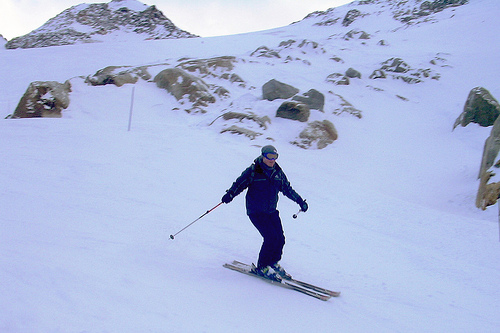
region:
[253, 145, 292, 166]
Person wearing gray hat.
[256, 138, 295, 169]
Blue goggles on person's face.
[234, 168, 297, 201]
Person wearing blue coat.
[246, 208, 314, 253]
Person wearing blue pants.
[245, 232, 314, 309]
2 skis on person's feet.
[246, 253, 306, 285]
Person wearing boots on feet.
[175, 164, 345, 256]
Person holding 2 poles.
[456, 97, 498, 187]
Large rocks to the right of skier.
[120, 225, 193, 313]
Ground covered in snow.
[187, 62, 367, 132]
Large pile of rocks behind skier.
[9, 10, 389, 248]
a skier on the mountain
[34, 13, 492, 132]
the slopes are rocky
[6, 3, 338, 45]
cloudy sky in the background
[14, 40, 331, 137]
dangerous rocks on the slopes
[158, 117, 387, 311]
the skier is dressed in blue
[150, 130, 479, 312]
the skier is moving down the mountain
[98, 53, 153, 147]
there is some line in the snow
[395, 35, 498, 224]
more rocks on the slope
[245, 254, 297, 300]
blue ski boots on this person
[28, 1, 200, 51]
a rocky hill on the slopes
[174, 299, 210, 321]
the snow is white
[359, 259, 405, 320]
the snow is white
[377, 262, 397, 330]
the snow is white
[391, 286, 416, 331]
the snow is white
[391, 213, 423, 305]
the snow is white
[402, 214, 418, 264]
the snow is white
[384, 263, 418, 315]
the snow is white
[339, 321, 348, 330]
the snow is white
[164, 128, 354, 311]
skier on a mountain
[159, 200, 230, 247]
ski pole in man's hand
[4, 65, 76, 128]
rocks on a mountain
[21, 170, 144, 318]
white snow on the ground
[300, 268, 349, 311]
front of a pair of skiis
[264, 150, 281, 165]
goggles on a skier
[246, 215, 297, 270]
blue snowpants on a man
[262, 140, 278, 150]
hat on a skier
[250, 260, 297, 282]
feet in the skiis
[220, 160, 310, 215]
blue jacket of a skier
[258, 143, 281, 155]
Woman wearing blue hat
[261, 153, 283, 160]
Woman wearing clear goggles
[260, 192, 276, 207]
Woman wearing blue coat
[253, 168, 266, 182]
Black patch on coat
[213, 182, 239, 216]
Woman has ski in hand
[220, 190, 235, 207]
Woman wearing black gloves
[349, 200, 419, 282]
White snow on ground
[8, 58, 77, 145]
Brown rock with snow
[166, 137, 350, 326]
Woman on silver skis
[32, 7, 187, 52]
Moutain rock with dirt and snow